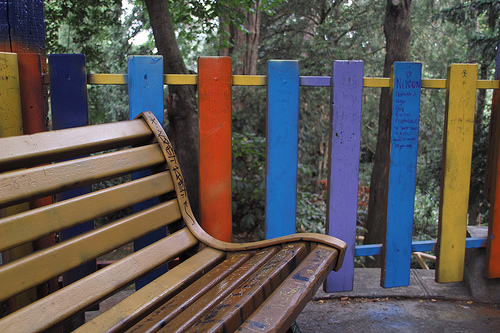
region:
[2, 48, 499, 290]
Multi-colored wooden picket fence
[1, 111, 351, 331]
An empty park bench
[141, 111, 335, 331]
Graffiti all over the bench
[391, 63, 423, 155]
Graffiti on the fence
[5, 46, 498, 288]
The fence is yellow, blue, purple and red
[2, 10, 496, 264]
Trees on the other side of the fence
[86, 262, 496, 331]
The walk is made of concrete.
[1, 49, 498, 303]
The fence doesn't reach the ground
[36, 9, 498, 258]
Many different types of leaves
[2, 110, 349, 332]
The wooden bench is stained a light color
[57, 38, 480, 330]
colorful fence in a park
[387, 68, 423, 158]
writing on a blue post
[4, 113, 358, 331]
bench in a park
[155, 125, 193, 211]
writing on a bench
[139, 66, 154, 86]
nail to a fence post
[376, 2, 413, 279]
trunk of a tree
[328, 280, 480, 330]
concrete ground under bench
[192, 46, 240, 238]
orange post of a fence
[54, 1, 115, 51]
green leaves on trees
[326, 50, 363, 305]
purple post of a fence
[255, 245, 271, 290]
There is brown that is in the bench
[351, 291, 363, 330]
There is a dark color grey in the cement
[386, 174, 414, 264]
There is a blue fence that is there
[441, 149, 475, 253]
There is a fence that is yellow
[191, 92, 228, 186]
There is a red fence that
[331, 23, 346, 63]
There is a dark green tree that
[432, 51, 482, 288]
yellow fence post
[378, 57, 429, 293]
blue fence post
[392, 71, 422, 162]
writing on blue fence post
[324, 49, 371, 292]
purple fence post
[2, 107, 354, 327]
wooden bench next to fence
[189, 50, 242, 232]
red fence post behind bench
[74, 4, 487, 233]
trees behind fence line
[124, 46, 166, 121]
blue post partially seen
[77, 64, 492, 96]
yellow beam holding colorful fence posts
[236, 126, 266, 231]
leaves on bushes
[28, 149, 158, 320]
Brown bench on patio.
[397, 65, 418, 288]
Blue post of fence.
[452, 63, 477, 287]
Yellow post of fence.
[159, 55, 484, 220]
Colorful fence around patio.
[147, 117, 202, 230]
Black writing on fence.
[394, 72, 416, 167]
Black writing on post.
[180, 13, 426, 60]
Trees behind fence.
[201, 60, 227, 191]
Orange post of fence around patio.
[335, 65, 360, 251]
Purple post of fence around patio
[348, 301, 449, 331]
Patio made of concrete.